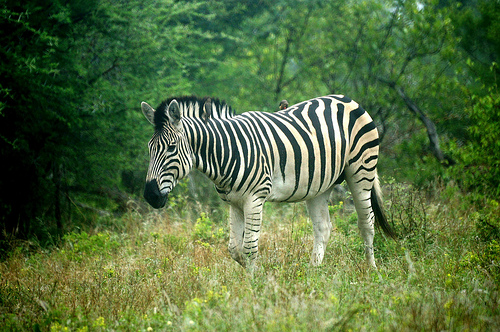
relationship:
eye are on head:
[166, 145, 177, 152] [139, 65, 201, 214]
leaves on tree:
[125, 30, 206, 89] [275, 7, 447, 86]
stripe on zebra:
[320, 92, 337, 186] [136, 88, 407, 273]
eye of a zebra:
[163, 142, 177, 151] [136, 88, 407, 273]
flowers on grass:
[373, 251, 484, 330] [58, 235, 225, 322]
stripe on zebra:
[320, 95, 335, 186] [139, 95, 396, 268]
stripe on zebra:
[346, 103, 363, 141] [139, 95, 396, 268]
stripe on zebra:
[363, 150, 377, 165] [139, 95, 396, 268]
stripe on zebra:
[255, 110, 287, 177] [139, 95, 396, 268]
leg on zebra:
[239, 196, 266, 276] [136, 88, 407, 273]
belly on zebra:
[263, 163, 344, 204] [136, 88, 407, 273]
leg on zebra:
[307, 191, 331, 263] [136, 88, 407, 273]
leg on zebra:
[346, 168, 377, 269] [136, 88, 407, 273]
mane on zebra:
[147, 90, 234, 130] [136, 88, 407, 273]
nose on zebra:
[142, 178, 170, 210] [136, 88, 407, 273]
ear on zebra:
[167, 99, 184, 123] [136, 88, 407, 273]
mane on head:
[147, 90, 234, 130] [136, 91, 200, 210]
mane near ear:
[147, 90, 234, 130] [165, 97, 182, 124]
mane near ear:
[147, 90, 234, 130] [138, 95, 157, 128]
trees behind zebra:
[3, 2, 498, 247] [136, 88, 407, 273]